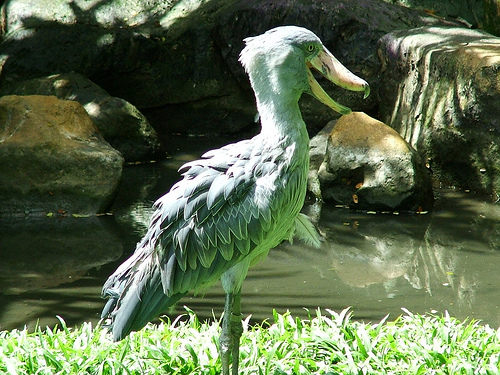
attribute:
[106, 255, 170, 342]
tail feather — gray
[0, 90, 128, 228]
rock — brown, large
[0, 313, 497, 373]
grass — green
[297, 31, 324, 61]
birds eye — open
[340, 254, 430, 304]
water — brown, murky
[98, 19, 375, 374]
eye — small, beady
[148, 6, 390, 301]
bird — gray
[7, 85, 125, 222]
rock — large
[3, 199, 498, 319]
water — dirty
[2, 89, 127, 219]
stones — large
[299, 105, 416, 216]
stones — large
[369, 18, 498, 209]
stones — large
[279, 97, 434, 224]
boulder — small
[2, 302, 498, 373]
grass — green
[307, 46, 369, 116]
beak — hooked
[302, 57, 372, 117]
mouth — open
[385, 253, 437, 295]
water — gray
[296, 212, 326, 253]
feather — small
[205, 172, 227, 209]
feathers — gray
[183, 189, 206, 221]
feathers — gray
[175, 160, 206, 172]
feathers — gray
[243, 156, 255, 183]
feathers — gray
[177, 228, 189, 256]
feathers — gray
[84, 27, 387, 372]
bird — gray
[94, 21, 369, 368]
bird — large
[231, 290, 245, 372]
leg — gray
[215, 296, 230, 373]
leg — gray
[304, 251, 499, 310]
water — dirty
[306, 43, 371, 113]
beak — big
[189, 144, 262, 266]
feathers — gray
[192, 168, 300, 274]
feathers — tons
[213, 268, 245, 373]
legs — skinny